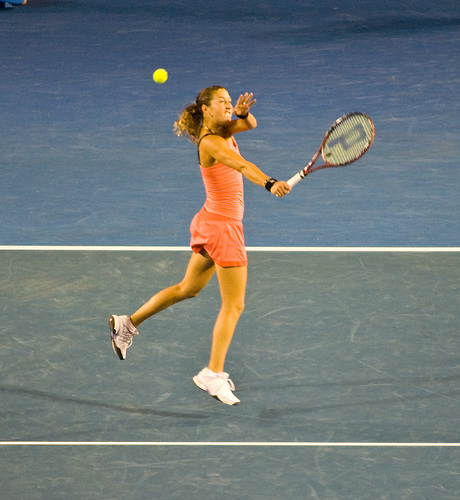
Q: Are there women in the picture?
A: Yes, there is a woman.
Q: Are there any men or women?
A: Yes, there is a woman.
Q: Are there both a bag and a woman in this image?
A: No, there is a woman but no bags.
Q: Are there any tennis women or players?
A: Yes, there is a tennis woman.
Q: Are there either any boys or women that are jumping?
A: Yes, the woman is jumping.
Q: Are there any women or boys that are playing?
A: Yes, the woman is playing.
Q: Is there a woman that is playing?
A: Yes, there is a woman that is playing.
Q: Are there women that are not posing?
A: Yes, there is a woman that is playing.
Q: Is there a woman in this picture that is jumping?
A: Yes, there is a woman that is jumping.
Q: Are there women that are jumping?
A: Yes, there is a woman that is jumping.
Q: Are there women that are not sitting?
A: Yes, there is a woman that is jumping.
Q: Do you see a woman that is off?
A: Yes, there is a woman that is off.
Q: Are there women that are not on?
A: Yes, there is a woman that is off.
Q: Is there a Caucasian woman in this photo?
A: Yes, there is a Caucasian woman.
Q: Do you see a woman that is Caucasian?
A: Yes, there is a woman that is caucasian.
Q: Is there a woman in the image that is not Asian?
A: Yes, there is an Caucasian woman.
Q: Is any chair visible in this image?
A: No, there are no chairs.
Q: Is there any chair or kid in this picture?
A: No, there are no chairs or children.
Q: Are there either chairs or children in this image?
A: No, there are no chairs or children.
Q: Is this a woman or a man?
A: This is a woman.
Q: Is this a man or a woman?
A: This is a woman.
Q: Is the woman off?
A: Yes, the woman is off.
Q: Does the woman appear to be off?
A: Yes, the woman is off.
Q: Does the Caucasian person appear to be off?
A: Yes, the woman is off.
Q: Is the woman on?
A: No, the woman is off.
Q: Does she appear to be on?
A: No, the woman is off.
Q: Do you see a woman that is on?
A: No, there is a woman but she is off.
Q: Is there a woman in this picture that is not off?
A: No, there is a woman but she is off.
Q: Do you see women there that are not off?
A: No, there is a woman but she is off.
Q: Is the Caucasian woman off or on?
A: The woman is off.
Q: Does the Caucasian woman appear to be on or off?
A: The woman is off.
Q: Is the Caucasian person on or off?
A: The woman is off.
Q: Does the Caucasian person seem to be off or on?
A: The woman is off.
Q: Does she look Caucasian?
A: Yes, the woman is caucasian.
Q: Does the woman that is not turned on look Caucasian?
A: Yes, the woman is caucasian.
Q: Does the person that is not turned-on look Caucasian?
A: Yes, the woman is caucasian.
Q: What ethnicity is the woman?
A: The woman is caucasian.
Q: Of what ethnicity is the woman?
A: The woman is caucasian.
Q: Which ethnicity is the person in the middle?
A: The woman is caucasian.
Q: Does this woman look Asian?
A: No, the woman is caucasian.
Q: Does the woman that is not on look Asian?
A: No, the woman is caucasian.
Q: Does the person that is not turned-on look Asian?
A: No, the woman is caucasian.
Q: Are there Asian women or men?
A: No, there is a woman but she is caucasian.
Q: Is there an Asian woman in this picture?
A: No, there is a woman but she is caucasian.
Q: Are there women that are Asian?
A: No, there is a woman but she is caucasian.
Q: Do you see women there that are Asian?
A: No, there is a woman but she is caucasian.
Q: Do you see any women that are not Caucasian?
A: No, there is a woman but she is caucasian.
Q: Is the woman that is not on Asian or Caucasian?
A: The woman is caucasian.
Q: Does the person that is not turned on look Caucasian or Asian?
A: The woman is caucasian.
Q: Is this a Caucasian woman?
A: Yes, this is a Caucasian woman.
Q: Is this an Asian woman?
A: No, this is a Caucasian woman.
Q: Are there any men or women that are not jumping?
A: No, there is a woman but she is jumping.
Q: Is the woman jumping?
A: Yes, the woman is jumping.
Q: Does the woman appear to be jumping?
A: Yes, the woman is jumping.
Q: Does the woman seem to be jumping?
A: Yes, the woman is jumping.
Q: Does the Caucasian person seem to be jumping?
A: Yes, the woman is jumping.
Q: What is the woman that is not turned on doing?
A: The woman is jumping.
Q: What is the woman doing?
A: The woman is jumping.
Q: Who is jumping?
A: The woman is jumping.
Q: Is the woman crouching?
A: No, the woman is jumping.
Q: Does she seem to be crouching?
A: No, the woman is jumping.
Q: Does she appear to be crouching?
A: No, the woman is jumping.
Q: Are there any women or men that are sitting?
A: No, there is a woman but she is jumping.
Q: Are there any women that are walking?
A: No, there is a woman but she is jumping.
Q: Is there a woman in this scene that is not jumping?
A: No, there is a woman but she is jumping.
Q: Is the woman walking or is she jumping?
A: The woman is jumping.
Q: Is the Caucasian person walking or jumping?
A: The woman is jumping.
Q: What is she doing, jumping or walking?
A: The woman is jumping.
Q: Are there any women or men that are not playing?
A: No, there is a woman but she is playing.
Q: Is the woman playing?
A: Yes, the woman is playing.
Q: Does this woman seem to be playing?
A: Yes, the woman is playing.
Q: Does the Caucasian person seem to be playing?
A: Yes, the woman is playing.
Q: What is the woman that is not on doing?
A: The woman is playing.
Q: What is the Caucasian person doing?
A: The woman is playing.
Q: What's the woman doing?
A: The woman is playing.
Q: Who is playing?
A: The woman is playing.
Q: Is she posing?
A: No, the woman is playing.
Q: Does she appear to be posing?
A: No, the woman is playing.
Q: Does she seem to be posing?
A: No, the woman is playing.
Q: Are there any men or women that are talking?
A: No, there is a woman but she is playing.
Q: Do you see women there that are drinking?
A: No, there is a woman but she is playing.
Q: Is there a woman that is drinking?
A: No, there is a woman but she is playing.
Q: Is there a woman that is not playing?
A: No, there is a woman but she is playing.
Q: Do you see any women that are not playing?
A: No, there is a woman but she is playing.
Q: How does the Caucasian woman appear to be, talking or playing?
A: The woman is playing.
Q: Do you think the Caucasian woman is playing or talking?
A: The woman is playing.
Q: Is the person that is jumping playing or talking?
A: The woman is playing.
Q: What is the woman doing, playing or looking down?
A: The woman is playing.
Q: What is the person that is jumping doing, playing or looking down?
A: The woman is playing.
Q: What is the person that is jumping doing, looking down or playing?
A: The woman is playing.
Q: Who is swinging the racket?
A: The woman is swinging the racket.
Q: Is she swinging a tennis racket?
A: Yes, the woman is swinging a tennis racket.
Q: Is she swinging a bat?
A: No, the woman is swinging a tennis racket.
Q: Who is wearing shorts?
A: The woman is wearing shorts.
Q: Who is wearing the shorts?
A: The woman is wearing shorts.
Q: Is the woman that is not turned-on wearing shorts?
A: Yes, the woman is wearing shorts.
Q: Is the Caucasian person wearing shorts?
A: Yes, the woman is wearing shorts.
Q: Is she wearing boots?
A: No, the woman is wearing shorts.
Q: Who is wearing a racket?
A: The woman is wearing a racket.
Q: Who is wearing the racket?
A: The woman is wearing a racket.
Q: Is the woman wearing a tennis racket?
A: Yes, the woman is wearing a tennis racket.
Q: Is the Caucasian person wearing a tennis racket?
A: Yes, the woman is wearing a tennis racket.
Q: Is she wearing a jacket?
A: No, the woman is wearing a tennis racket.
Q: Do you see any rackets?
A: Yes, there is a racket.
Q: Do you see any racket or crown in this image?
A: Yes, there is a racket.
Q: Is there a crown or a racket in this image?
A: Yes, there is a racket.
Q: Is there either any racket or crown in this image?
A: Yes, there is a racket.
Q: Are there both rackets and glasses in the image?
A: No, there is a racket but no glasses.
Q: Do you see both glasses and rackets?
A: No, there is a racket but no glasses.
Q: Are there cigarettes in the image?
A: No, there are no cigarettes.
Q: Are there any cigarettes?
A: No, there are no cigarettes.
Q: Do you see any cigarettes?
A: No, there are no cigarettes.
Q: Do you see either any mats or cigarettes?
A: No, there are no cigarettes or mats.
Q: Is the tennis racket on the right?
A: Yes, the tennis racket is on the right of the image.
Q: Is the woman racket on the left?
A: No, the racket is on the right of the image.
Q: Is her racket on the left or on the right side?
A: The tennis racket is on the right of the image.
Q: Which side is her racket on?
A: The racket is on the right of the image.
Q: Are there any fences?
A: No, there are no fences.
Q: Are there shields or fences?
A: No, there are no fences or shields.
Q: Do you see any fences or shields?
A: No, there are no fences or shields.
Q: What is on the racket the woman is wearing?
A: The letter is on the tennis racket.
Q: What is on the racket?
A: The letter is on the tennis racket.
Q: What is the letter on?
A: The letter is on the tennis racket.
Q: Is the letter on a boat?
A: No, the letter is on the tennis racket.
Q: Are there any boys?
A: No, there are no boys.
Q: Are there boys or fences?
A: No, there are no boys or fences.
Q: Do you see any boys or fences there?
A: No, there are no boys or fences.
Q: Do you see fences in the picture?
A: No, there are no fences.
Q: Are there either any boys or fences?
A: No, there are no fences or boys.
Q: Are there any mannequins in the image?
A: No, there are no mannequins.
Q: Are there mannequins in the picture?
A: No, there are no mannequins.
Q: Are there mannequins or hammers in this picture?
A: No, there are no mannequins or hammers.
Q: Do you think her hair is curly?
A: Yes, the hair is curly.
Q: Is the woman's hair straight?
A: No, the hair is curly.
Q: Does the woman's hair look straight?
A: No, the hair is curly.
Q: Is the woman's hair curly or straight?
A: The hair is curly.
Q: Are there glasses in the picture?
A: No, there are no glasses.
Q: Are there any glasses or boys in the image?
A: No, there are no glasses or boys.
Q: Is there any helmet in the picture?
A: No, there are no helmets.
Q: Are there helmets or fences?
A: No, there are no helmets or fences.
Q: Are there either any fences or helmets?
A: No, there are no helmets or fences.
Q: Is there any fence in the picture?
A: No, there are no fences.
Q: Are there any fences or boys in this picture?
A: No, there are no fences or boys.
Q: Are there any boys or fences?
A: No, there are no fences or boys.